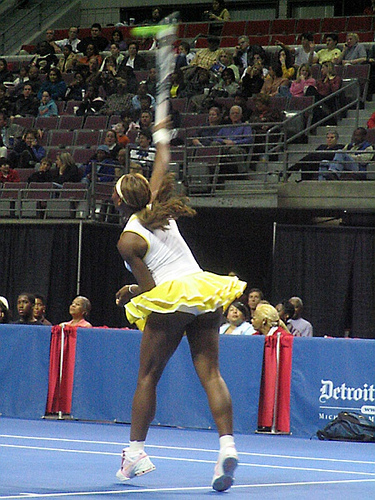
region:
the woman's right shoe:
[205, 434, 244, 490]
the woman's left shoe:
[112, 443, 156, 481]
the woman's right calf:
[203, 378, 234, 420]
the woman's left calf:
[129, 383, 156, 427]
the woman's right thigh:
[190, 329, 222, 370]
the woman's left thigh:
[137, 310, 183, 372]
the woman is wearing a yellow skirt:
[118, 271, 248, 326]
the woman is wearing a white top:
[115, 211, 205, 287]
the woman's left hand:
[112, 284, 138, 308]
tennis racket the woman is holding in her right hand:
[144, 23, 179, 141]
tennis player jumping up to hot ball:
[100, 20, 248, 493]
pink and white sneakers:
[114, 446, 155, 481]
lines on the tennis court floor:
[3, 432, 374, 498]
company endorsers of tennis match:
[313, 374, 374, 404]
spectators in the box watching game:
[0, 282, 317, 333]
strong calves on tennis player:
[128, 387, 248, 421]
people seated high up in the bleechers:
[0, 1, 371, 181]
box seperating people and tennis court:
[1, 322, 372, 432]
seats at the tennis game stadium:
[1, 181, 108, 213]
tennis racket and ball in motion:
[130, 20, 183, 125]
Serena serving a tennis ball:
[80, 14, 253, 498]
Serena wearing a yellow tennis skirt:
[91, 169, 258, 335]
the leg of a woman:
[187, 333, 243, 494]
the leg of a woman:
[96, 326, 164, 482]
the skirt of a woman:
[119, 277, 251, 330]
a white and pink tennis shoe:
[94, 436, 159, 483]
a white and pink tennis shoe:
[201, 429, 240, 490]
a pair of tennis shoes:
[107, 430, 239, 488]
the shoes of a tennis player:
[99, 426, 252, 498]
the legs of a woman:
[98, 316, 263, 498]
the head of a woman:
[104, 158, 198, 239]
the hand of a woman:
[109, 278, 134, 314]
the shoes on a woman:
[102, 418, 300, 492]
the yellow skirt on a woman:
[136, 253, 279, 337]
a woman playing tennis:
[83, 150, 335, 477]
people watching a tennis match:
[12, 231, 361, 349]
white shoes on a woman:
[95, 418, 298, 492]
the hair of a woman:
[109, 163, 218, 242]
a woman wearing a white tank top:
[98, 180, 244, 356]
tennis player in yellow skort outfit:
[96, 114, 250, 494]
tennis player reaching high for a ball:
[107, 114, 241, 494]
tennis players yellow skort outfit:
[110, 196, 250, 338]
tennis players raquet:
[150, 25, 177, 102]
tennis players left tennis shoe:
[107, 448, 156, 481]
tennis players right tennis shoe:
[205, 443, 242, 494]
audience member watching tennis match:
[315, 125, 372, 179]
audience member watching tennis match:
[30, 158, 54, 183]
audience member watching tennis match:
[304, 127, 342, 177]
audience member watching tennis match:
[338, 30, 367, 73]